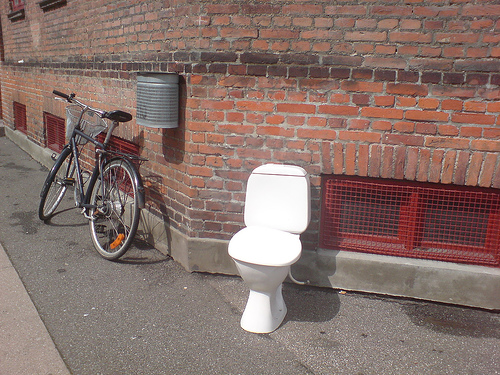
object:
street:
[0, 135, 499, 372]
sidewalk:
[0, 125, 184, 369]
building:
[1, 0, 491, 298]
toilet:
[222, 159, 317, 339]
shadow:
[141, 175, 184, 264]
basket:
[62, 109, 129, 141]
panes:
[91, 130, 143, 190]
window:
[90, 130, 140, 192]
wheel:
[24, 144, 86, 228]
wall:
[41, 0, 128, 84]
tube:
[282, 265, 317, 291]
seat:
[97, 105, 137, 123]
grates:
[321, 172, 498, 269]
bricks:
[362, 53, 408, 68]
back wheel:
[82, 154, 146, 261]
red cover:
[323, 180, 498, 267]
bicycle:
[37, 83, 154, 270]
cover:
[206, 220, 315, 272]